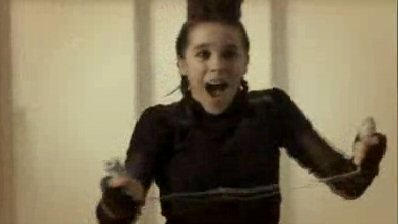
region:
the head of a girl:
[163, 4, 290, 128]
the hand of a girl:
[310, 122, 395, 195]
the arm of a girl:
[102, 68, 188, 209]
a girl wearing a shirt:
[91, 75, 320, 200]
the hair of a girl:
[160, 0, 283, 84]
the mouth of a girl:
[188, 61, 248, 106]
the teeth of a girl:
[194, 70, 244, 109]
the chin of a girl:
[193, 93, 247, 118]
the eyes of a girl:
[185, 29, 280, 68]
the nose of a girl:
[188, 56, 240, 87]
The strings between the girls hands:
[106, 166, 395, 221]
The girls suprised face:
[169, 24, 247, 114]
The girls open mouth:
[200, 75, 230, 103]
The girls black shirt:
[119, 105, 379, 216]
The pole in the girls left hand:
[93, 149, 131, 203]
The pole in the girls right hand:
[357, 108, 393, 178]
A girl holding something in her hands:
[89, 23, 392, 218]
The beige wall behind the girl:
[7, 9, 391, 217]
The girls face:
[175, 24, 243, 130]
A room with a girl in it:
[37, 3, 388, 222]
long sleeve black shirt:
[94, 85, 386, 221]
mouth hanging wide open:
[203, 75, 231, 102]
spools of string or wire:
[89, 119, 371, 202]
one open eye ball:
[185, 39, 215, 64]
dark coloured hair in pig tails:
[169, 13, 258, 134]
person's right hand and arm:
[90, 103, 161, 222]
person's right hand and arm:
[260, 68, 392, 202]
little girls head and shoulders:
[128, 10, 287, 131]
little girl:
[82, 15, 382, 222]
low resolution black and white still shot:
[0, 2, 393, 222]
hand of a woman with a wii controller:
[95, 156, 145, 221]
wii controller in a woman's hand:
[353, 112, 383, 172]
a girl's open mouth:
[202, 75, 229, 99]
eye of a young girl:
[194, 46, 209, 59]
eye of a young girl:
[221, 44, 235, 58]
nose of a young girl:
[210, 52, 223, 73]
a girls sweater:
[94, 86, 387, 221]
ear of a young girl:
[243, 51, 250, 73]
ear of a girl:
[175, 53, 189, 76]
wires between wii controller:
[133, 170, 357, 208]